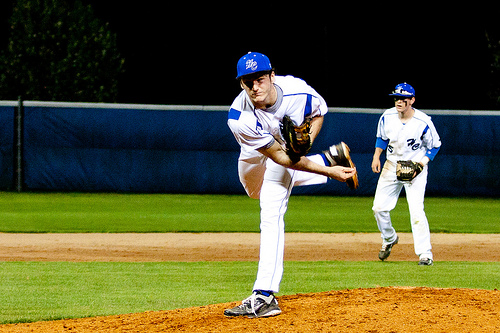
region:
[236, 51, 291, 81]
a blue baseball cap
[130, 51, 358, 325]
a baseball player on the field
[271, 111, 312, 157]
a catcher's mit on the player's left hand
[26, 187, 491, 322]
a baseball field with freshly mowed grass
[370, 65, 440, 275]
a baseball player in motion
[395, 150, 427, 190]
a catcher's mit on the player's left hand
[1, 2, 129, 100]
a tree behind the blue net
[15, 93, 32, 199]
a metal post in the ground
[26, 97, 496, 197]
a fence that is covered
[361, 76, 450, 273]
a baseball player with a blue and white uniform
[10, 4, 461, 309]
two players on a baseball team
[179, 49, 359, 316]
this player is the pitcher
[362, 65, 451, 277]
this is an outfield man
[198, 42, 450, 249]
these player's are wearing blue and white uniforms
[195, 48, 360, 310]
this player's team colors are blue and white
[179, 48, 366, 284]
he is using a specific pitching style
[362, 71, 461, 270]
this player is focused on something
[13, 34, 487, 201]
a padded blue wall is behind the players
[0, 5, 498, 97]
this part of the stadium area has dark green trees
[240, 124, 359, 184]
the pitcher's arm is slant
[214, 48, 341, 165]
a baseball player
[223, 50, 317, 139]
a man wearing a blue hat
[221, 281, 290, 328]
a nike sneaker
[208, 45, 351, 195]
a baseball player holding a baseball glove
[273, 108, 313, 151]
a baseball glove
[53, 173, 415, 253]
green grass on a baseball field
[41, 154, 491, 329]
a baseball field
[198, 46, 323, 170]
a man wearing a white and blue shirt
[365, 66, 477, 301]
a man wearing white pants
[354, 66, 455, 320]
a man wearing sneakers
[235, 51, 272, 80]
blue and white cap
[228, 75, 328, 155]
white and blue jersey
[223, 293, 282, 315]
grey and white cleat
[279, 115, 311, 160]
brown leather baseball glove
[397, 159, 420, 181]
black leather baseball glove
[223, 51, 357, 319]
man pitching in baseball game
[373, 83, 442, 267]
man playing on baseball field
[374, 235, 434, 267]
black and white cleats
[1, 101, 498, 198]
blue barrier on fence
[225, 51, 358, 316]
man standing on pitchers mound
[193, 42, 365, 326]
baseball pitcher wearing team colors of blue and white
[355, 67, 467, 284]
baseball fielder wearing home uniform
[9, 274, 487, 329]
pitcher's mound at a baseball park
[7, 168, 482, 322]
the turf of a baseball field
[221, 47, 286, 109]
male, adult baseball player wearing ball cap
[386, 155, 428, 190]
baseball glove on adult, male human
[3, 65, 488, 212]
the fence of a baseball field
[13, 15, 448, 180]
dark sky at a baseball park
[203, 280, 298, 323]
Nike athletic shoe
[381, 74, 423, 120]
baseball player awaiting hit